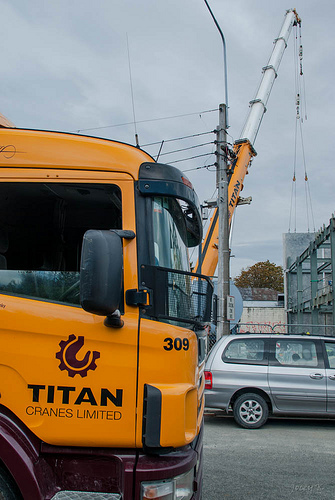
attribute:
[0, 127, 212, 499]
truck — yellow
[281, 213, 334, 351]
building — being built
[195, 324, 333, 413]
van — silver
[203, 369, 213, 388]
light — tail, red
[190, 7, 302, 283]
crane — behind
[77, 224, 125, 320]
mirror — side, black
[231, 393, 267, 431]
tire — back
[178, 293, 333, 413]
van — parked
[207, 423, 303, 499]
asphalt — paved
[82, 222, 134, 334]
mirror — side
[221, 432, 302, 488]
road — asphalt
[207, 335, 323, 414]
car — gray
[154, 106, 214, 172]
lines — power